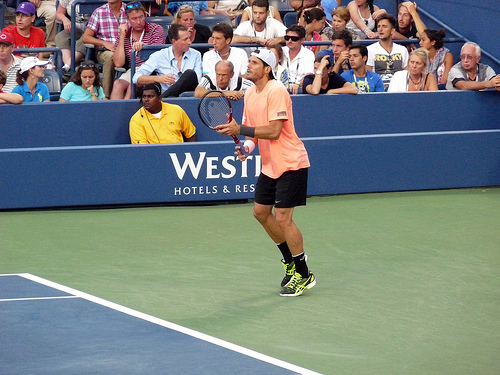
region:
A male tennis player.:
[209, 44, 332, 301]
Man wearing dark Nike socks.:
[278, 245, 320, 277]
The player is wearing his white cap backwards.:
[236, 46, 293, 88]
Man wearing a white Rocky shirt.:
[361, 8, 413, 72]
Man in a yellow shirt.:
[121, 80, 199, 146]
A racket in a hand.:
[191, 76, 249, 163]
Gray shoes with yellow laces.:
[268, 254, 326, 302]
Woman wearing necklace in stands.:
[388, 43, 443, 91]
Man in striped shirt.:
[111, 0, 168, 60]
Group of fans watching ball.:
[308, 10, 499, 137]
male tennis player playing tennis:
[192, 53, 349, 308]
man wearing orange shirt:
[236, 82, 313, 186]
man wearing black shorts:
[243, 163, 319, 216]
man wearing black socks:
[272, 241, 319, 273]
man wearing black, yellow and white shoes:
[271, 260, 326, 305]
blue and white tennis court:
[6, 283, 228, 368]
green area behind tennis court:
[322, 207, 489, 347]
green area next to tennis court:
[64, 222, 251, 291]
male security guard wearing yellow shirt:
[119, 109, 201, 139]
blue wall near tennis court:
[332, 102, 485, 172]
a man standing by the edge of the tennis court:
[197, 47, 321, 300]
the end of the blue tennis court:
[2, 272, 322, 373]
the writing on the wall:
[165, 150, 265, 195]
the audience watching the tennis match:
[2, 3, 499, 91]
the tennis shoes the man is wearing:
[274, 256, 319, 303]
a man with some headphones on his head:
[122, 84, 195, 147]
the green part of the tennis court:
[28, 180, 492, 373]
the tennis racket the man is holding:
[192, 88, 246, 153]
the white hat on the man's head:
[250, 44, 280, 80]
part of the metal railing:
[64, 0, 101, 80]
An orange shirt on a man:
[236, 80, 311, 176]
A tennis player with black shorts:
[195, 45, 325, 295]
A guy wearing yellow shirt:
[120, 75, 196, 142]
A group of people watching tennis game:
[0, 0, 495, 100]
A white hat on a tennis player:
[246, 40, 286, 80]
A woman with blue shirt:
[55, 56, 105, 101]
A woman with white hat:
[10, 50, 46, 100]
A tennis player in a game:
[196, 46, 324, 293]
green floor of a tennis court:
[0, 192, 498, 372]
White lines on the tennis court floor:
[0, 270, 327, 374]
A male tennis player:
[202, 44, 317, 311]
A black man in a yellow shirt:
[121, 80, 200, 152]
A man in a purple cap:
[3, 1, 45, 48]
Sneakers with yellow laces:
[275, 255, 319, 302]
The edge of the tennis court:
[1, 267, 306, 374]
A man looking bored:
[449, 37, 499, 93]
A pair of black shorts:
[248, 161, 310, 211]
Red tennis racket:
[190, 86, 245, 155]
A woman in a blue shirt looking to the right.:
[10, 52, 52, 103]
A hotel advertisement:
[161, 148, 268, 201]